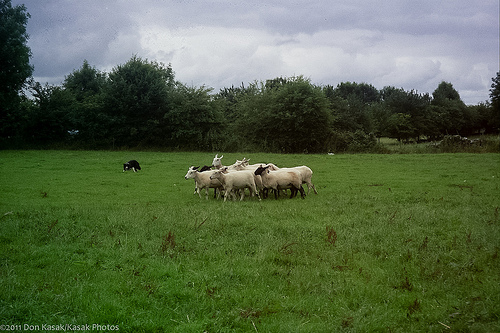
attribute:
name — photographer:
[19, 307, 64, 328]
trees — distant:
[1, 53, 498, 151]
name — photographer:
[20, 314, 71, 331]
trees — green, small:
[205, 64, 402, 158]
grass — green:
[5, 149, 495, 326]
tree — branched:
[248, 72, 334, 155]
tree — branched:
[98, 55, 177, 140]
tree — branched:
[325, 76, 380, 133]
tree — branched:
[171, 83, 208, 150]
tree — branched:
[210, 79, 255, 146]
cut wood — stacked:
[430, 135, 489, 152]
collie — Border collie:
[120, 159, 140, 173]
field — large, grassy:
[118, 209, 456, 307]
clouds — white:
[13, 0, 498, 90]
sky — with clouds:
[0, 1, 495, 108]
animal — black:
[123, 158, 144, 173]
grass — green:
[261, 207, 411, 314]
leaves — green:
[10, 23, 39, 80]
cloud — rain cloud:
[11, 2, 146, 86]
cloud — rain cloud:
[228, 30, 495, 94]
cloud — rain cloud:
[145, 23, 267, 95]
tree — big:
[259, 64, 325, 151]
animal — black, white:
[93, 140, 160, 185]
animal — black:
[118, 155, 143, 175]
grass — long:
[11, 189, 497, 306]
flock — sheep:
[181, 152, 321, 202]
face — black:
[249, 164, 266, 174]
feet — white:
[120, 166, 141, 188]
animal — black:
[113, 147, 142, 179]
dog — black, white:
[124, 157, 151, 174]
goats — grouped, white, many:
[185, 151, 316, 206]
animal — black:
[117, 148, 153, 178]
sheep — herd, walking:
[182, 150, 316, 203]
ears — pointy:
[212, 153, 224, 161]